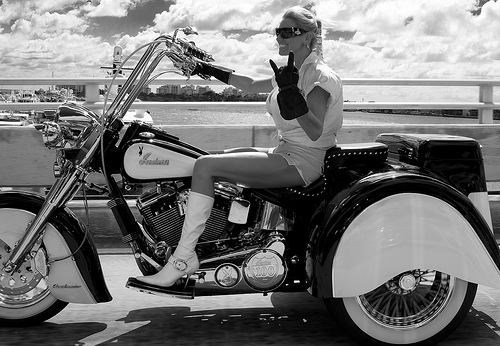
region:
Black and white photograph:
[6, 7, 489, 336]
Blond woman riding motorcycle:
[8, 4, 491, 330]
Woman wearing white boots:
[131, 5, 343, 291]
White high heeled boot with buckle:
[134, 188, 221, 290]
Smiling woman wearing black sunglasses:
[262, 3, 338, 125]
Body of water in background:
[152, 110, 266, 123]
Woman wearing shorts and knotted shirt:
[259, 5, 345, 190]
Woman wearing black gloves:
[171, 5, 329, 125]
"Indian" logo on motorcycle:
[132, 143, 182, 168]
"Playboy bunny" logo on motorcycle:
[134, 142, 146, 159]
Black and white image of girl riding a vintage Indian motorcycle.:
[3, 2, 498, 341]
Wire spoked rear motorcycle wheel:
[333, 267, 478, 344]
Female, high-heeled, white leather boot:
[133, 189, 218, 288]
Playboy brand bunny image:
[136, 143, 147, 156]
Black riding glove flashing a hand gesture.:
[266, 50, 310, 122]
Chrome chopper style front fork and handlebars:
[1, 23, 226, 278]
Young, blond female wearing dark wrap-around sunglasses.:
[273, 5, 325, 60]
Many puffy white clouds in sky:
[1, 3, 111, 76]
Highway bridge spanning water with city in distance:
[1, 75, 499, 125]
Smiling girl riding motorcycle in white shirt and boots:
[127, 5, 346, 295]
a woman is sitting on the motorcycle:
[8, 25, 488, 341]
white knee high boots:
[129, 184, 213, 301]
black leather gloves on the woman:
[259, 50, 323, 126]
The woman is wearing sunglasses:
[253, 1, 338, 71]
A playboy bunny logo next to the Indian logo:
[131, 140, 179, 177]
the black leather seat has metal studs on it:
[280, 143, 407, 208]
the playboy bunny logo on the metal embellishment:
[214, 262, 239, 292]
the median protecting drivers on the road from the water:
[5, 69, 499, 179]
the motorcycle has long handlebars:
[20, 28, 495, 335]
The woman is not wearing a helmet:
[243, 6, 356, 168]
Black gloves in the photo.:
[267, 49, 307, 122]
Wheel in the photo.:
[330, 193, 481, 340]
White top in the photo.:
[269, 59, 342, 152]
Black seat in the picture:
[332, 134, 395, 167]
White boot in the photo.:
[138, 187, 211, 284]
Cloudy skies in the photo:
[361, 17, 464, 67]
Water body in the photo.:
[173, 107, 213, 122]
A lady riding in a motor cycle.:
[136, 4, 349, 287]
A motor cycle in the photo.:
[0, 1, 497, 331]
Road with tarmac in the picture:
[32, 304, 276, 341]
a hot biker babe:
[117, 3, 354, 300]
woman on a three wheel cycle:
[0, 13, 494, 345]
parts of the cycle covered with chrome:
[190, 200, 297, 292]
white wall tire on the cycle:
[330, 273, 477, 344]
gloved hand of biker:
[265, 50, 308, 125]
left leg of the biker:
[180, 143, 320, 255]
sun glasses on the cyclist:
[267, 20, 326, 45]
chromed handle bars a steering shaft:
[7, 17, 219, 273]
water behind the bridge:
[37, 98, 484, 130]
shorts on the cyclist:
[263, 133, 335, 190]